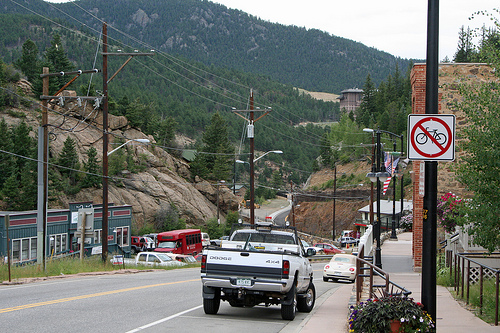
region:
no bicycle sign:
[407, 116, 455, 166]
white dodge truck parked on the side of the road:
[197, 226, 314, 317]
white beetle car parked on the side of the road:
[322, 251, 357, 281]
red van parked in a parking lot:
[152, 231, 199, 257]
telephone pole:
[231, 90, 269, 237]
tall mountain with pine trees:
[2, 0, 416, 205]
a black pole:
[422, 2, 437, 329]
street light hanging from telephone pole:
[105, 136, 149, 154]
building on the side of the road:
[2, 204, 132, 271]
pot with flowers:
[341, 289, 434, 327]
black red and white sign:
[392, 110, 462, 175]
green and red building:
[32, 198, 140, 283]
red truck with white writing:
[145, 210, 208, 265]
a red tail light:
[275, 255, 295, 280]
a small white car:
[297, 238, 364, 310]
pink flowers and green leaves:
[417, 188, 470, 242]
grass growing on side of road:
[3, 251, 124, 296]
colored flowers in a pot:
[335, 293, 427, 332]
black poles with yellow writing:
[414, 165, 449, 310]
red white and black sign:
[378, 126, 465, 177]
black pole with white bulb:
[356, 135, 398, 270]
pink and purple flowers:
[412, 191, 467, 239]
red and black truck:
[120, 218, 211, 278]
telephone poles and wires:
[19, 98, 185, 203]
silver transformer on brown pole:
[223, 108, 273, 148]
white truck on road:
[195, 211, 317, 331]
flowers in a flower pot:
[342, 285, 452, 325]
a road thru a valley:
[236, 163, 327, 240]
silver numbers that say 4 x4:
[256, 255, 283, 270]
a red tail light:
[267, 254, 303, 284]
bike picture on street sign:
[410, 116, 456, 162]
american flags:
[377, 155, 406, 192]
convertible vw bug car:
[330, 243, 363, 276]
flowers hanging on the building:
[401, 202, 417, 231]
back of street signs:
[69, 197, 100, 266]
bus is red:
[155, 227, 197, 259]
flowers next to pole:
[365, 293, 432, 330]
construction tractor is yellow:
[239, 193, 264, 216]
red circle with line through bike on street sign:
[415, 113, 464, 160]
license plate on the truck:
[238, 268, 263, 293]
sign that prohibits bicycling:
[398, 107, 459, 171]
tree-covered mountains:
[3, 0, 390, 130]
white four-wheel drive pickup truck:
[198, 212, 318, 322]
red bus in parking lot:
[152, 225, 204, 258]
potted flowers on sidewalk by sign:
[347, 286, 435, 329]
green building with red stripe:
[3, 204, 136, 262]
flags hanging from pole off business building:
[376, 143, 406, 194]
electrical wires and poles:
[47, 34, 391, 144]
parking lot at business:
[132, 220, 216, 263]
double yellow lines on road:
[20, 265, 197, 314]